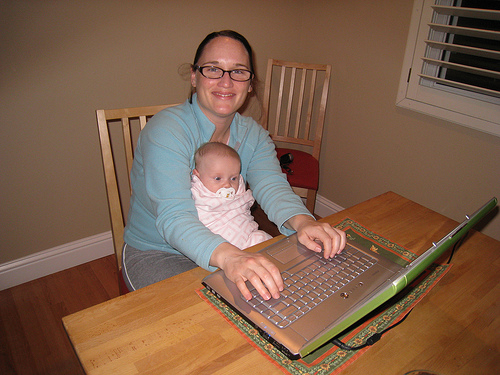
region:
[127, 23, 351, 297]
woman holding baby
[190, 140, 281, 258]
baby bundled up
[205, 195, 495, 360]
laptop on table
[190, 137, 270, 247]
baby with pacifier in mouth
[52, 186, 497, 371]
wooden table on which laptop is sitting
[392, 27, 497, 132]
louvered window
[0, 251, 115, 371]
hardwood flooring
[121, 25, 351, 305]
woman working at computer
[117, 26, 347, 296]
woman wearing eyeglasses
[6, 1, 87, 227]
taupe wall behind woman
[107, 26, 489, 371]
woman holding a baby typing on a keyboard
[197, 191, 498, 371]
laptop computer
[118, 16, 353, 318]
woman wearing glasses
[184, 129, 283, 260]
baby sucking on a pacifier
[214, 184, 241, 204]
baby pacifier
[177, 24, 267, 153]
woman with glasses wearing a blue shirt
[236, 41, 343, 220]
wooden chair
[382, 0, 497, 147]
wooden mini-blinds in a window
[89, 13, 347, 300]
woman sitting in a wooden chair holding a baby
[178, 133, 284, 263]
baby in a pink blanket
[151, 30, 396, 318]
mother and baby in front of laptop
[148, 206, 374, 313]
hands on silver keyboard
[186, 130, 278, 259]
baby swaddled in pink and white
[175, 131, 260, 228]
pacifier in baby's mouth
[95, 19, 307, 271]
mother sitting on wooden chair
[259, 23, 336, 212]
spare chair in corner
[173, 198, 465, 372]
orange and green place mat under laptop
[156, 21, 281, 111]
mother wearing brown eyeglasses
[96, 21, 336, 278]
mother wearing blue top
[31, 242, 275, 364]
wooden floor and desk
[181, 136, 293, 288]
a baby wrapped in a blanket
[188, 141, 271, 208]
the baby has blue eyes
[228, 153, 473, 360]
this is a laptop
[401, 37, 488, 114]
this is a window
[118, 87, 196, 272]
she has a blue shirt on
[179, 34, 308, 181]
the woman is smiling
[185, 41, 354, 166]
she has glasses on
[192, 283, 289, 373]
a place mat on the table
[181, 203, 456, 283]
she is typing on the laptop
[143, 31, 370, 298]
the baby is on her lap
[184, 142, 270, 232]
little baby girl bundled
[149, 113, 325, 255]
light blue work out jacket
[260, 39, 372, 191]
empty wooden chair with red seat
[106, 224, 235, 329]
gray sweat pats with blue line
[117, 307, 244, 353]
light wooden table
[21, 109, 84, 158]
tan wall paint color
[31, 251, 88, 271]
white wooden baseboard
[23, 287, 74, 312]
cherry colored wooden floor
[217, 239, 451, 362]
green lap top computer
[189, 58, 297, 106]
round oval brown glasses